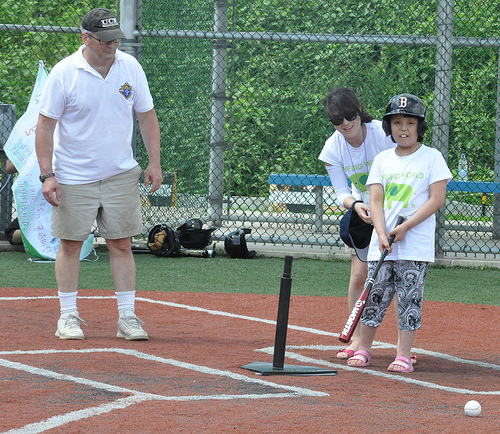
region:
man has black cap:
[67, 6, 129, 39]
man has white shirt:
[22, 39, 137, 159]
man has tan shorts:
[25, 169, 159, 251]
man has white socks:
[69, 280, 131, 325]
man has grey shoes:
[52, 316, 132, 343]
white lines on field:
[55, 343, 181, 430]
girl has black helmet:
[381, 96, 454, 146]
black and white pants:
[358, 220, 423, 342]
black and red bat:
[307, 220, 421, 364]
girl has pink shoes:
[337, 323, 412, 384]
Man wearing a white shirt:
[22, 13, 169, 348]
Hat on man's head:
[77, 11, 134, 50]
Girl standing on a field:
[339, 89, 451, 381]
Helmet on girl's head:
[381, 83, 428, 138]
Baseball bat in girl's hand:
[339, 202, 415, 348]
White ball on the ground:
[440, 393, 499, 421]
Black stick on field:
[242, 246, 323, 388]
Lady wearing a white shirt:
[310, 82, 395, 345]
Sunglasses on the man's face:
[322, 100, 372, 126]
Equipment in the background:
[141, 201, 271, 271]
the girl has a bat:
[352, 258, 453, 422]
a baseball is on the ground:
[445, 378, 497, 418]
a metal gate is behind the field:
[176, 11, 314, 148]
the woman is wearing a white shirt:
[314, 133, 404, 210]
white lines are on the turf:
[156, 294, 238, 412]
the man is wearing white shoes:
[42, 306, 225, 376]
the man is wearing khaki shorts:
[52, 159, 224, 354]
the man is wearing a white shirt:
[45, 48, 222, 195]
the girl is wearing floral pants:
[320, 285, 411, 362]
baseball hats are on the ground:
[142, 173, 342, 285]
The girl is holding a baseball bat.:
[333, 83, 447, 390]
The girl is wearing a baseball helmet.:
[338, 85, 438, 382]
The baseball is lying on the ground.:
[444, 375, 485, 432]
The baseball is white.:
[419, 380, 499, 425]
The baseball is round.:
[437, 379, 497, 431]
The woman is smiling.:
[313, 77, 390, 198]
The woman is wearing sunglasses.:
[314, 73, 383, 185]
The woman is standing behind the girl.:
[302, 77, 457, 384]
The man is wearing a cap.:
[23, 4, 197, 394]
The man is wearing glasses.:
[36, 4, 166, 348]